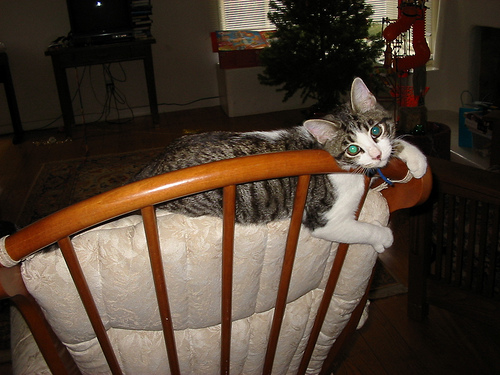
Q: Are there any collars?
A: Yes, there is a collar.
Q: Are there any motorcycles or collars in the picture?
A: Yes, there is a collar.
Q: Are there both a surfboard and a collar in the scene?
A: No, there is a collar but no surfboards.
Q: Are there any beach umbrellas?
A: No, there are no beach umbrellas.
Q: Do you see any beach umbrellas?
A: No, there are no beach umbrellas.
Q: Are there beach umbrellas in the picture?
A: No, there are no beach umbrellas.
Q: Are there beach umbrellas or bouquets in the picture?
A: No, there are no beach umbrellas or bouquets.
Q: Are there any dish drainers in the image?
A: No, there are no dish drainers.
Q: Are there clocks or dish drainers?
A: No, there are no dish drainers or clocks.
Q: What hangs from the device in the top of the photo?
A: The cords hang from the television.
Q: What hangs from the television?
A: The cords hang from the television.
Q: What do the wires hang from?
A: The wires hang from the television.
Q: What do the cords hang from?
A: The wires hang from the television.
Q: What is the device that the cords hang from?
A: The device is a television.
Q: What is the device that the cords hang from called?
A: The device is a television.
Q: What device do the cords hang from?
A: The cords hang from the television.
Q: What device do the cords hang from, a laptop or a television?
A: The cords hang from a television.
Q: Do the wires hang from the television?
A: Yes, the wires hang from the television.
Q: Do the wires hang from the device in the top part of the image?
A: Yes, the wires hang from the television.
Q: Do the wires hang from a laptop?
A: No, the wires hang from the television.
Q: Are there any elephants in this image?
A: No, there are no elephants.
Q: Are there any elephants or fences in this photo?
A: No, there are no elephants or fences.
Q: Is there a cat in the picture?
A: Yes, there is a cat.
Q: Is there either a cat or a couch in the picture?
A: Yes, there is a cat.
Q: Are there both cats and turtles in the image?
A: No, there is a cat but no turtles.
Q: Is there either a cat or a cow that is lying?
A: Yes, the cat is lying.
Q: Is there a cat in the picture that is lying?
A: Yes, there is a cat that is lying.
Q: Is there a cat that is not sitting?
A: Yes, there is a cat that is lying.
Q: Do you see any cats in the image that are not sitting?
A: Yes, there is a cat that is lying .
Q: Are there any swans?
A: No, there are no swans.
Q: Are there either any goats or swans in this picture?
A: No, there are no swans or goats.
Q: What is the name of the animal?
A: The animal is a cat.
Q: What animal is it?
A: The animal is a cat.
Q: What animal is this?
A: That is a cat.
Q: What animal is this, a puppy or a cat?
A: That is a cat.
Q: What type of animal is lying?
A: The animal is a cat.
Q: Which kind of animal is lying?
A: The animal is a cat.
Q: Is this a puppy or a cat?
A: This is a cat.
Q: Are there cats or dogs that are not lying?
A: No, there is a cat but it is lying.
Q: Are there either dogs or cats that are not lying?
A: No, there is a cat but it is lying.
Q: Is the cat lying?
A: Yes, the cat is lying.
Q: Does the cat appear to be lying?
A: Yes, the cat is lying.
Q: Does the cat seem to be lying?
A: Yes, the cat is lying.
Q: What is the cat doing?
A: The cat is lying.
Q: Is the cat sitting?
A: No, the cat is lying.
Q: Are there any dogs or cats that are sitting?
A: No, there is a cat but it is lying.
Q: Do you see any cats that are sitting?
A: No, there is a cat but it is lying.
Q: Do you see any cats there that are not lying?
A: No, there is a cat but it is lying.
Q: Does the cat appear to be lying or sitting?
A: The cat is lying.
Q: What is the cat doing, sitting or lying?
A: The cat is lying.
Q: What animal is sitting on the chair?
A: The cat is sitting on the chair.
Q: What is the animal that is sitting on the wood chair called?
A: The animal is a cat.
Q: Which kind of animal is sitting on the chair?
A: The animal is a cat.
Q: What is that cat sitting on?
A: The cat is sitting on the chair.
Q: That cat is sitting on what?
A: The cat is sitting on the chair.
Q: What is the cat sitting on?
A: The cat is sitting on the chair.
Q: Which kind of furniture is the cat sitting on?
A: The cat is sitting on the chair.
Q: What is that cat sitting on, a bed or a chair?
A: The cat is sitting on a chair.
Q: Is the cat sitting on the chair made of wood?
A: Yes, the cat is sitting on the chair.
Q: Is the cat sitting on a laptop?
A: No, the cat is sitting on the chair.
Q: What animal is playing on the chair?
A: The cat is playing on the chair.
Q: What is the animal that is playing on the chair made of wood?
A: The animal is a cat.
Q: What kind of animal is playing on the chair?
A: The animal is a cat.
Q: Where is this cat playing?
A: The cat is playing on the chair.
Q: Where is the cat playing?
A: The cat is playing on the chair.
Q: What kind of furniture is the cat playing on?
A: The cat is playing on the chair.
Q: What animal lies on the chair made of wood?
A: The cat lies on the chair.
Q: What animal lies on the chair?
A: The cat lies on the chair.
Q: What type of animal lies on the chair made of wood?
A: The animal is a cat.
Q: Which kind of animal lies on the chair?
A: The animal is a cat.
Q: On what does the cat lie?
A: The cat lies on the chair.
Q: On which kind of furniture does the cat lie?
A: The cat lies on the chair.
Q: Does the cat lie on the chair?
A: Yes, the cat lies on the chair.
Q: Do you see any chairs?
A: Yes, there is a chair.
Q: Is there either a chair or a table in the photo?
A: Yes, there is a chair.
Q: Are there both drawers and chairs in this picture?
A: No, there is a chair but no drawers.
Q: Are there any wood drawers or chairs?
A: Yes, there is a wood chair.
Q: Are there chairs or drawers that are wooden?
A: Yes, the chair is wooden.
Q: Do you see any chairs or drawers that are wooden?
A: Yes, the chair is wooden.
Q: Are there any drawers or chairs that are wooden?
A: Yes, the chair is wooden.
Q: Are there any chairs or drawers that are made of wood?
A: Yes, the chair is made of wood.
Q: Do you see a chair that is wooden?
A: Yes, there is a wood chair.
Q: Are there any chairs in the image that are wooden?
A: Yes, there is a chair that is wooden.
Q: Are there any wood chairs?
A: Yes, there is a chair that is made of wood.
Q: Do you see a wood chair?
A: Yes, there is a chair that is made of wood.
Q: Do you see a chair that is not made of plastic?
A: Yes, there is a chair that is made of wood.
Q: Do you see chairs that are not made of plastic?
A: Yes, there is a chair that is made of wood.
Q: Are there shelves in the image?
A: No, there are no shelves.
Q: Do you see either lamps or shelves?
A: No, there are no shelves or lamps.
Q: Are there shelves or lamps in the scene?
A: No, there are no shelves or lamps.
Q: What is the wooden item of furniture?
A: The piece of furniture is a chair.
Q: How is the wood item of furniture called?
A: The piece of furniture is a chair.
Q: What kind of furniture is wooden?
A: The furniture is a chair.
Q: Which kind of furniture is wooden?
A: The furniture is a chair.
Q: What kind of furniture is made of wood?
A: The furniture is a chair.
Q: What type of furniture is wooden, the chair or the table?
A: The chair is wooden.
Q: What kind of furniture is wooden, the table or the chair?
A: The chair is wooden.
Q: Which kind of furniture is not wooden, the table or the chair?
A: The table is not wooden.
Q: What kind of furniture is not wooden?
A: The furniture is a table.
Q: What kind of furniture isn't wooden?
A: The furniture is a table.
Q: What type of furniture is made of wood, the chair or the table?
A: The chair is made of wood.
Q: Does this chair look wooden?
A: Yes, the chair is wooden.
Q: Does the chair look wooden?
A: Yes, the chair is wooden.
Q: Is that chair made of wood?
A: Yes, the chair is made of wood.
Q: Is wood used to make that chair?
A: Yes, the chair is made of wood.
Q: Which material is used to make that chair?
A: The chair is made of wood.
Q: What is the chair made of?
A: The chair is made of wood.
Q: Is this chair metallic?
A: No, the chair is wooden.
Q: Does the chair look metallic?
A: No, the chair is wooden.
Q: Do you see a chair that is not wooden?
A: No, there is a chair but it is wooden.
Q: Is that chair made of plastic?
A: No, the chair is made of wood.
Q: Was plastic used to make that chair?
A: No, the chair is made of wood.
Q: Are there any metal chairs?
A: No, there is a chair but it is made of wood.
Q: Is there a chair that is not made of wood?
A: No, there is a chair but it is made of wood.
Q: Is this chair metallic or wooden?
A: The chair is wooden.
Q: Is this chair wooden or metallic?
A: The chair is wooden.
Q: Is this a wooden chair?
A: Yes, this is a wooden chair.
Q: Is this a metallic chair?
A: No, this is a wooden chair.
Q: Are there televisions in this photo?
A: Yes, there is a television.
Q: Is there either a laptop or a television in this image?
A: Yes, there is a television.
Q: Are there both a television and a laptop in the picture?
A: No, there is a television but no laptops.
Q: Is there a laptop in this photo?
A: No, there are no laptops.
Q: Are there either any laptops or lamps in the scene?
A: No, there are no laptops or lamps.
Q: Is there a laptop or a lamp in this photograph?
A: No, there are no laptops or lamps.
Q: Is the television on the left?
A: Yes, the television is on the left of the image.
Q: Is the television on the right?
A: No, the television is on the left of the image.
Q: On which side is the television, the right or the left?
A: The television is on the left of the image.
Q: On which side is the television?
A: The television is on the left of the image.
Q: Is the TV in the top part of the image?
A: Yes, the TV is in the top of the image.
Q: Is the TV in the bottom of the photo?
A: No, the TV is in the top of the image.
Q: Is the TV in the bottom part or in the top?
A: The TV is in the top of the image.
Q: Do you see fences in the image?
A: No, there are no fences.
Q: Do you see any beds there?
A: No, there are no beds.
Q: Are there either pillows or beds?
A: No, there are no beds or pillows.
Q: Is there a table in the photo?
A: Yes, there is a table.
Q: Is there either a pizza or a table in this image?
A: Yes, there is a table.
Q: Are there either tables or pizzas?
A: Yes, there is a table.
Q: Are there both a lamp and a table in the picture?
A: No, there is a table but no lamps.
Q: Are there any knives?
A: No, there are no knives.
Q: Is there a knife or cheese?
A: No, there are no knives or cheese.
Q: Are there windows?
A: Yes, there is a window.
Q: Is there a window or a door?
A: Yes, there is a window.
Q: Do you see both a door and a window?
A: No, there is a window but no doors.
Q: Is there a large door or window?
A: Yes, there is a large window.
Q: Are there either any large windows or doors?
A: Yes, there is a large window.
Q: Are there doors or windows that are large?
A: Yes, the window is large.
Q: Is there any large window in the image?
A: Yes, there is a large window.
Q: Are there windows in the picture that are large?
A: Yes, there is a window that is large.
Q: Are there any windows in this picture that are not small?
A: Yes, there is a large window.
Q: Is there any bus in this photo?
A: No, there are no buses.